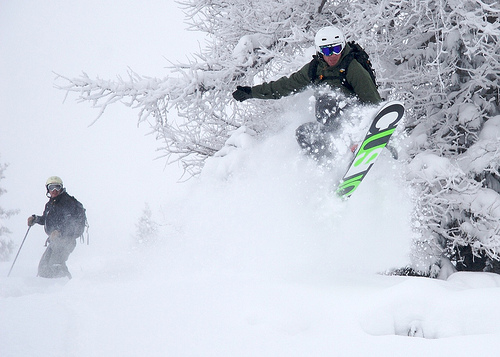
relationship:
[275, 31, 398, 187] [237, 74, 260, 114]
man has gloves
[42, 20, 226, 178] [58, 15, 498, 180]
snow on tree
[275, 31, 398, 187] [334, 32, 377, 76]
man wears backpack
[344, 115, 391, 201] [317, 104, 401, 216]
letters on board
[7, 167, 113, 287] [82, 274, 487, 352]
man on ground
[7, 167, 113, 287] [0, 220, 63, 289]
man holds poles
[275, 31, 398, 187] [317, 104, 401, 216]
man on board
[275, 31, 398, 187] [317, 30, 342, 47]
man wears helmet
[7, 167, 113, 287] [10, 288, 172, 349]
man standing in snow